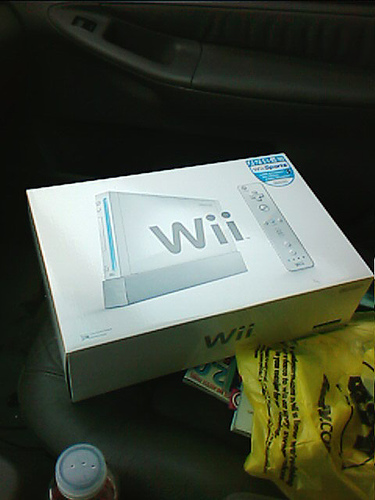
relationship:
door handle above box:
[50, 15, 195, 85] [21, 150, 372, 406]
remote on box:
[237, 178, 314, 274] [21, 150, 372, 406]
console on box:
[94, 189, 249, 311] [21, 150, 372, 406]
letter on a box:
[146, 214, 211, 255] [21, 150, 372, 406]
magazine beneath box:
[181, 350, 237, 399] [21, 150, 372, 406]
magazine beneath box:
[229, 380, 252, 435] [21, 150, 372, 406]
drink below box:
[43, 441, 122, 498] [21, 150, 372, 406]